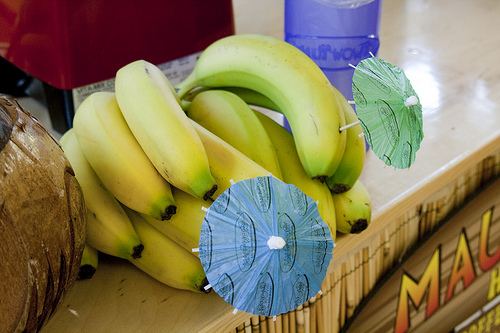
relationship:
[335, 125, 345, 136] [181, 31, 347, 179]
puncture in banana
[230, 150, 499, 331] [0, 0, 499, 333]
bamboo on counter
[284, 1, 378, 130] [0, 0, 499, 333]
cup on counter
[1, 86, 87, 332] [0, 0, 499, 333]
bowl on counter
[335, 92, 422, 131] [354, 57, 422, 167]
handle on paper umbrella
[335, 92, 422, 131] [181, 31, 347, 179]
handle stuck into banana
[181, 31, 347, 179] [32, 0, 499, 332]
banana on counter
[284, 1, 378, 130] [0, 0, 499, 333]
cup on counter top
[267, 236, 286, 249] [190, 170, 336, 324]
tip on umbrella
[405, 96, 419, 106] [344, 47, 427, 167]
tip on umbrella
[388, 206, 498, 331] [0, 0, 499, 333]
lettered sign on counter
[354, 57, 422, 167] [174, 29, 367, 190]
paper umbrella stuck into banana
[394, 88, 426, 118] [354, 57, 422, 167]
tip on paper umbrella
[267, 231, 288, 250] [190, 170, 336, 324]
tip on umbrella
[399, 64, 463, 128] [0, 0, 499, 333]
light on counter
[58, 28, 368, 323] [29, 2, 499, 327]
banana sitting on stand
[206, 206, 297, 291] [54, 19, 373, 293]
umbrella stuck in banana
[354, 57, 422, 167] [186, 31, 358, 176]
paper umbrella stuck in banana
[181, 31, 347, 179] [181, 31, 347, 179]
banana attached to banana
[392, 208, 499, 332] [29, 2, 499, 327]
lettering on stand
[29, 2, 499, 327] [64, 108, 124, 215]
stand holding banana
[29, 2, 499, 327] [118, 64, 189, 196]
stand holding banana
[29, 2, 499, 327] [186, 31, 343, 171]
stand holding banana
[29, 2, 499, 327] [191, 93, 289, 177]
stand holding banana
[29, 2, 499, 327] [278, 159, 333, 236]
stand holding banana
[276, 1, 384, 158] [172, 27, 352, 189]
cup next to banana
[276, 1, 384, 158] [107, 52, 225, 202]
cup next to banana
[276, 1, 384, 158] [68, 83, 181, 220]
cup next to banana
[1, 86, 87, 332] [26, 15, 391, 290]
bowl next to bananas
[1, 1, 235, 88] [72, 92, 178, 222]
cloth next to banana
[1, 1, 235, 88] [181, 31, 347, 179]
cloth next to banana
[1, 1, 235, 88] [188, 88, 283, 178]
cloth next to banana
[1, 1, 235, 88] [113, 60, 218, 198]
cloth next to banana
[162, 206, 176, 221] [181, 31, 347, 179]
end in banana